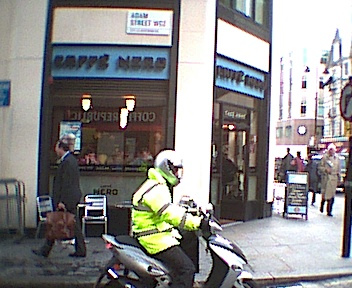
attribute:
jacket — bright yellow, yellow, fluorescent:
[127, 167, 203, 256]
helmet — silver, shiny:
[154, 149, 186, 187]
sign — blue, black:
[49, 42, 171, 82]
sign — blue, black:
[213, 51, 268, 100]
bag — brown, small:
[44, 205, 78, 242]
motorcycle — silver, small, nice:
[93, 195, 257, 287]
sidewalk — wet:
[220, 178, 352, 280]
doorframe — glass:
[210, 84, 266, 222]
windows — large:
[47, 102, 171, 173]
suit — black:
[39, 151, 86, 254]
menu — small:
[283, 171, 311, 220]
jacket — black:
[282, 154, 294, 169]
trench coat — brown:
[318, 154, 342, 199]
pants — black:
[146, 228, 202, 287]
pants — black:
[37, 203, 86, 254]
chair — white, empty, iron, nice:
[36, 195, 54, 239]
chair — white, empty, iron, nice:
[81, 193, 109, 241]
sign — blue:
[0, 79, 12, 107]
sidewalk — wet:
[1, 233, 139, 285]